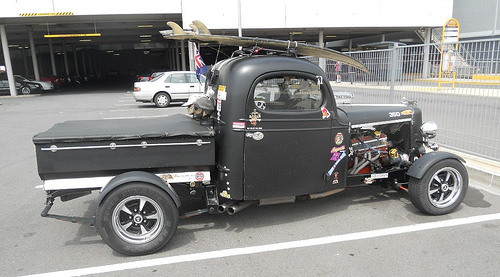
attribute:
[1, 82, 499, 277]
pavement — grey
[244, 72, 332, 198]
door — black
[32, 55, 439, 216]
truck — parked, black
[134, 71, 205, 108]
car — white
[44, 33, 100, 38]
bar — yellow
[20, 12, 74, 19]
warning bar — yellow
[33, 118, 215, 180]
bed — covered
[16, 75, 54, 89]
car — white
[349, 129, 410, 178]
engine — exposed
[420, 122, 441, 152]
headlight — chrome